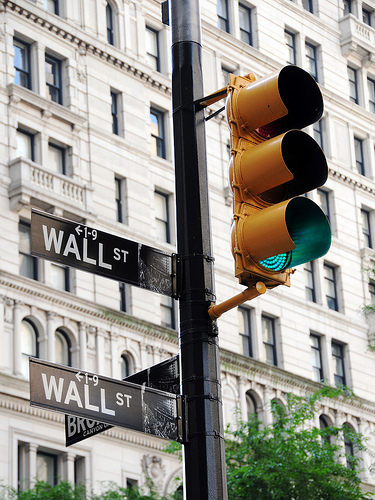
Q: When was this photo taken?
A: Daytime.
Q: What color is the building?
A: White.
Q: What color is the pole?
A: Black.